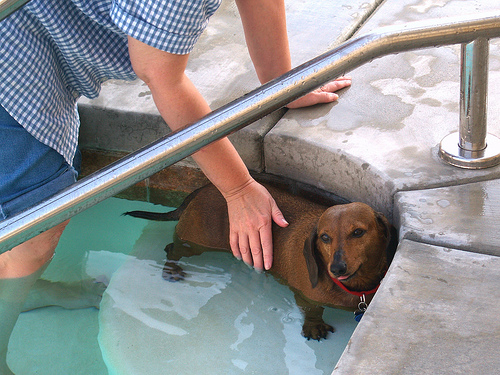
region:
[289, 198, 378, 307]
Dog wearing red collar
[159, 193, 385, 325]
Small dog in pool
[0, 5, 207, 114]
Blue and white checked shirt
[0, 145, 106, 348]
Bare feet in pool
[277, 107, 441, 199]
Curved wet concrete pavement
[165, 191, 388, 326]
Short brown dog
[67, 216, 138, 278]
The water is bluish green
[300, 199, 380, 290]
The dog has brown eyes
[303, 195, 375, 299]
Dog with tongue sticking out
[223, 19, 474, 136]
Wet silver railing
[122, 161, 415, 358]
dog in a pool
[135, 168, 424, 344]
little dog in a pool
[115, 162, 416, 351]
small dog in a pool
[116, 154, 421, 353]
brown dog in a pool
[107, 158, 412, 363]
little brown dog in a pool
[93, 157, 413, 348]
cute dog in a pool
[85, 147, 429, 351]
adorable dog in a pool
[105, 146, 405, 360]
attractive dog in a pool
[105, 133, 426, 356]
wet dog in a pool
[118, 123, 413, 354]
dog relaxing in a pool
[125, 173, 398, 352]
a dog in a swimming pool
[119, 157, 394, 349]
legs of dog are in the water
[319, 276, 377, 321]
red collar with a tag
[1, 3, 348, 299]
woman petting a dog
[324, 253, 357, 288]
tip of tongue can be seen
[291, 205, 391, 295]
long floppy ears of dog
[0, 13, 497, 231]
handrail of swimming pool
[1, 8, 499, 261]
handrail is silver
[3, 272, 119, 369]
feet of woman in water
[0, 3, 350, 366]
woman wears a squared blue shirt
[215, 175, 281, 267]
a persons hand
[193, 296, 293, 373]
shadow in the water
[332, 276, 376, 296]
red collar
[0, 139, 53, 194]
person is wearing blue shorts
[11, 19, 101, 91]
a blue and white checkered shirt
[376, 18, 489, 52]
a metal pole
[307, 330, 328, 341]
the dogs nails are black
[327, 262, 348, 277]
the dogs nose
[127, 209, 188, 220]
the dogs tail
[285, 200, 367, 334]
the dog is in the water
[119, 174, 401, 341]
weiner dog!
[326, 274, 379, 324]
little red dog collar with tags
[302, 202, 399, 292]
cute little doggy face sticking its tongue out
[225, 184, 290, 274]
elderly woman's right hand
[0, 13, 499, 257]
chrome hand railing leading to the water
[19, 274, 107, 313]
normal foot that looks super long in the water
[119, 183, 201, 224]
wet little doggy tail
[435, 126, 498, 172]
base and anchor of the chrome hand rail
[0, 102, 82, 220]
blue jeans rolled into shorts so they don't get wet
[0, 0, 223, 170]
light blue and white plaid shirt